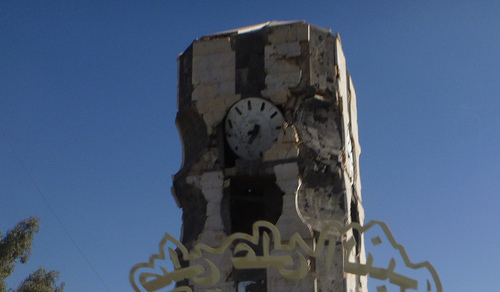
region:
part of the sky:
[440, 65, 441, 72]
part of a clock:
[254, 103, 264, 121]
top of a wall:
[324, 115, 336, 131]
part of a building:
[228, 61, 238, 79]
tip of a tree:
[21, 226, 34, 229]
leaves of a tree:
[33, 271, 48, 278]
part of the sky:
[119, 195, 133, 232]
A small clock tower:
[161, 27, 388, 289]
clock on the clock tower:
[223, 82, 293, 164]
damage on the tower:
[171, 90, 362, 258]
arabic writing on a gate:
[121, 194, 450, 290]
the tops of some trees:
[1, 205, 60, 290]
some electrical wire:
[12, 142, 129, 290]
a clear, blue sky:
[6, 2, 498, 280]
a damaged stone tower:
[172, 18, 378, 290]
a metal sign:
[107, 200, 494, 290]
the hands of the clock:
[240, 120, 265, 142]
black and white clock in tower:
[220, 95, 287, 159]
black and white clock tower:
[193, 44, 344, 88]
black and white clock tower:
[186, 161, 343, 225]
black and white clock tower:
[172, 220, 362, 287]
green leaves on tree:
[7, 212, 64, 287]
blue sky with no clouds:
[8, 12, 163, 146]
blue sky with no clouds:
[13, 122, 164, 209]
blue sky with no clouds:
[57, 141, 134, 258]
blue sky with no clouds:
[364, 11, 476, 186]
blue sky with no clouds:
[401, 122, 484, 242]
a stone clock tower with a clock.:
[166, 27, 373, 289]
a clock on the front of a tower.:
[212, 86, 300, 177]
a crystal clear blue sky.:
[0, 0, 496, 287]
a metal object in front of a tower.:
[126, 200, 442, 290]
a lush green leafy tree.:
[0, 206, 70, 291]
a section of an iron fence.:
[225, 213, 298, 270]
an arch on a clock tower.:
[206, 165, 286, 265]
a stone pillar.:
[267, 155, 309, 230]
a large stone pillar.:
[182, 152, 227, 238]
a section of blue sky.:
[84, 123, 131, 163]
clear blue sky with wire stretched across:
[5, 123, 113, 290]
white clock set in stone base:
[214, 85, 301, 171]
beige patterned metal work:
[108, 216, 454, 291]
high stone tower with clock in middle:
[161, 6, 376, 290]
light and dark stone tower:
[165, 15, 362, 177]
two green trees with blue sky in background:
[1, 204, 64, 290]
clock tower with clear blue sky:
[82, 11, 456, 212]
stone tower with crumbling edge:
[173, 18, 364, 195]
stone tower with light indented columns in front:
[173, 158, 366, 287]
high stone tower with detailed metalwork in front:
[131, 9, 443, 290]